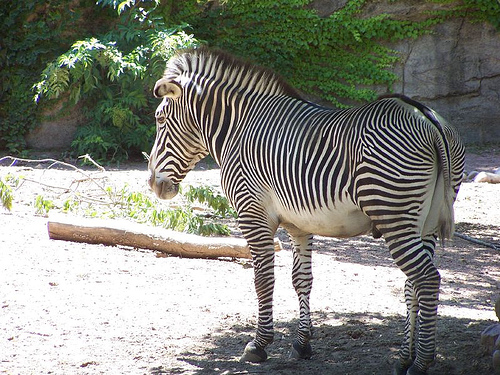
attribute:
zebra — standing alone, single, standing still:
[142, 60, 467, 360]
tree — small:
[42, 15, 215, 178]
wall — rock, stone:
[0, 0, 497, 152]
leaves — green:
[4, 4, 440, 164]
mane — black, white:
[163, 54, 305, 91]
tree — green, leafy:
[31, 0, 208, 168]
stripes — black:
[265, 126, 343, 188]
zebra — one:
[122, 47, 473, 373]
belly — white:
[281, 194, 367, 243]